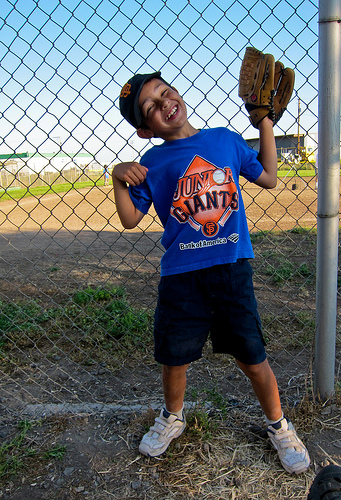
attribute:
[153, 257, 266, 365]
shorts — dark blue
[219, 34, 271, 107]
hat — black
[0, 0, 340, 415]
fence — wire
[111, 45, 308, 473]
kid — smiling